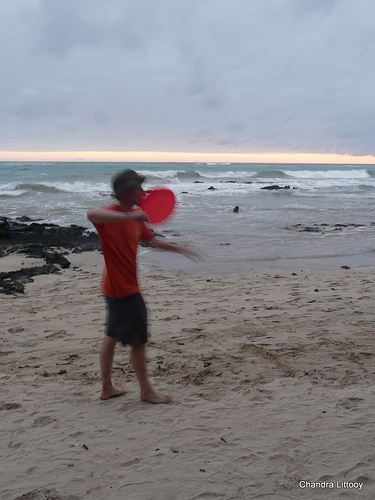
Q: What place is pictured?
A: It is a beach.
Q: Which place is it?
A: It is a beach.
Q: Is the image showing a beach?
A: Yes, it is showing a beach.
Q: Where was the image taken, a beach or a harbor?
A: It was taken at a beach.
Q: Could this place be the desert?
A: No, it is the beach.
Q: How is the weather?
A: It is cloudy.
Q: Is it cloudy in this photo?
A: Yes, it is cloudy.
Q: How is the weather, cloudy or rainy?
A: It is cloudy.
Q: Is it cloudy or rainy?
A: It is cloudy.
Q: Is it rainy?
A: No, it is cloudy.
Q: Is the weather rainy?
A: No, it is cloudy.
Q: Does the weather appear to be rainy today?
A: No, it is cloudy.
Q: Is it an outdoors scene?
A: Yes, it is outdoors.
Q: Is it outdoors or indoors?
A: It is outdoors.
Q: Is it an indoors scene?
A: No, it is outdoors.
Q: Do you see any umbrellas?
A: No, there are no umbrellas.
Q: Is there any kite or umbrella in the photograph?
A: No, there are no umbrellas or kites.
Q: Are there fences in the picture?
A: No, there are no fences.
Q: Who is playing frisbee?
A: The man is playing frisbee.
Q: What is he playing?
A: The man is playing frisbee.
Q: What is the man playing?
A: The man is playing frisbee.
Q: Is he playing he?
A: Yes, the man is playing frisbee.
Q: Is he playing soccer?
A: No, the man is playing frisbee.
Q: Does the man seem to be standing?
A: Yes, the man is standing.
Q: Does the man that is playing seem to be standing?
A: Yes, the man is standing.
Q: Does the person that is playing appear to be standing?
A: Yes, the man is standing.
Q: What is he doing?
A: The man is standing.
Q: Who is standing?
A: The man is standing.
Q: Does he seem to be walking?
A: No, the man is standing.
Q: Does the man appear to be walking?
A: No, the man is standing.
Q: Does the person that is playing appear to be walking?
A: No, the man is standing.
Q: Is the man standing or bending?
A: The man is standing.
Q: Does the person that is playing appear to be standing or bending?
A: The man is standing.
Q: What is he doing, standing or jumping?
A: The man is standing.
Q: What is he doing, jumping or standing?
A: The man is standing.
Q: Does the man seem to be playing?
A: Yes, the man is playing.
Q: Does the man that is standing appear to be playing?
A: Yes, the man is playing.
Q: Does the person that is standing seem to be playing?
A: Yes, the man is playing.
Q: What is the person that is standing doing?
A: The man is playing.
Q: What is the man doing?
A: The man is playing.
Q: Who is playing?
A: The man is playing.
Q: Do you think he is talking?
A: No, the man is playing.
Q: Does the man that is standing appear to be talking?
A: No, the man is playing.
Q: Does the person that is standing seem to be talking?
A: No, the man is playing.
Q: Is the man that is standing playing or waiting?
A: The man is playing.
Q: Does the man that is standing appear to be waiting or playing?
A: The man is playing.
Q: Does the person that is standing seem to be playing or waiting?
A: The man is playing.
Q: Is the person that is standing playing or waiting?
A: The man is playing.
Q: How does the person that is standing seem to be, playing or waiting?
A: The man is playing.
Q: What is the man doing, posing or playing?
A: The man is playing.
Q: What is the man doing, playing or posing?
A: The man is playing.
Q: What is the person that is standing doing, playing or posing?
A: The man is playing.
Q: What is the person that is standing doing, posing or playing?
A: The man is playing.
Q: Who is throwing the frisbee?
A: The man is throwing the frisbee.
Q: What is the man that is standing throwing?
A: The man is throwing the frisbee.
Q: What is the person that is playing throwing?
A: The man is throwing the frisbee.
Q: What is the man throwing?
A: The man is throwing the frisbee.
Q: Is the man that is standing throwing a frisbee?
A: Yes, the man is throwing a frisbee.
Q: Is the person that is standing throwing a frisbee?
A: Yes, the man is throwing a frisbee.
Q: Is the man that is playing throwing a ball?
A: No, the man is throwing a frisbee.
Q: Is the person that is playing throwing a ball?
A: No, the man is throwing a frisbee.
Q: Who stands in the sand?
A: The man stands in the sand.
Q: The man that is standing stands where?
A: The man stands in the sand.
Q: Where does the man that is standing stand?
A: The man stands in the sand.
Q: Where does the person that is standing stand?
A: The man stands in the sand.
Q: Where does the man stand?
A: The man stands in the sand.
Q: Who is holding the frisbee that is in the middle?
A: The man is holding the frisbee.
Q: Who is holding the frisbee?
A: The man is holding the frisbee.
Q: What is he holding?
A: The man is holding the frisbee.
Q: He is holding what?
A: The man is holding the frisbee.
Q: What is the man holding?
A: The man is holding the frisbee.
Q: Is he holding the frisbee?
A: Yes, the man is holding the frisbee.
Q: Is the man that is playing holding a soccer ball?
A: No, the man is holding the frisbee.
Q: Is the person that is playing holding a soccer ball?
A: No, the man is holding the frisbee.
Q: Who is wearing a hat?
A: The man is wearing a hat.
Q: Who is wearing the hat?
A: The man is wearing a hat.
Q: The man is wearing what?
A: The man is wearing a hat.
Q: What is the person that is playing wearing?
A: The man is wearing a hat.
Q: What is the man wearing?
A: The man is wearing a hat.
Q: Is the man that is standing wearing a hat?
A: Yes, the man is wearing a hat.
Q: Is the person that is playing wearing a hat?
A: Yes, the man is wearing a hat.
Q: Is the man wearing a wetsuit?
A: No, the man is wearing a hat.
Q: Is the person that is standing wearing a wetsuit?
A: No, the man is wearing a hat.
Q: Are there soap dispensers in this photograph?
A: No, there are no soap dispensers.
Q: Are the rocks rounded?
A: Yes, the rocks are rounded.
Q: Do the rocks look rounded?
A: Yes, the rocks are rounded.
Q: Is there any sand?
A: Yes, there is sand.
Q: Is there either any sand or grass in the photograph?
A: Yes, there is sand.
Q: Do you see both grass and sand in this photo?
A: No, there is sand but no grass.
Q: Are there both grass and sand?
A: No, there is sand but no grass.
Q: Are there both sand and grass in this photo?
A: No, there is sand but no grass.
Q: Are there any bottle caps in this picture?
A: No, there are no bottle caps.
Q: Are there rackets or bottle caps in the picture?
A: No, there are no bottle caps or rackets.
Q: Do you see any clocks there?
A: No, there are no clocks.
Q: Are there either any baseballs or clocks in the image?
A: No, there are no clocks or baseballs.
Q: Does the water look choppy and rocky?
A: Yes, the water is choppy and rocky.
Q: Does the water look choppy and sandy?
A: No, the water is choppy but rocky.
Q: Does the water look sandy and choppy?
A: No, the water is choppy but rocky.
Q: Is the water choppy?
A: Yes, the water is choppy.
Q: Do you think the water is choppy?
A: Yes, the water is choppy.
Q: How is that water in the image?
A: The water is choppy.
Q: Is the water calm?
A: No, the water is choppy.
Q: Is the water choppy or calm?
A: The water is choppy.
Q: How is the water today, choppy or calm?
A: The water is choppy.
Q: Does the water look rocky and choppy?
A: Yes, the water is rocky and choppy.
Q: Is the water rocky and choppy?
A: Yes, the water is rocky and choppy.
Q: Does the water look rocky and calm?
A: No, the water is rocky but choppy.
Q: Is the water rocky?
A: Yes, the water is rocky.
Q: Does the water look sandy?
A: No, the water is rocky.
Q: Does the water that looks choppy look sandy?
A: No, the water is rocky.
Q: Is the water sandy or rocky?
A: The water is rocky.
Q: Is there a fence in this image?
A: No, there are no fences.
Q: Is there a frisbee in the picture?
A: Yes, there is a frisbee.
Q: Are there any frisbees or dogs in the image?
A: Yes, there is a frisbee.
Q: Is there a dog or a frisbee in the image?
A: Yes, there is a frisbee.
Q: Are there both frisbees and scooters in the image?
A: No, there is a frisbee but no scooters.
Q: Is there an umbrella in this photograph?
A: No, there are no umbrellas.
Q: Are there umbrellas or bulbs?
A: No, there are no umbrellas or bulbs.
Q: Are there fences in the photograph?
A: No, there are no fences.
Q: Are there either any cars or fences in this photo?
A: No, there are no fences or cars.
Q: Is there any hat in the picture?
A: Yes, there is a hat.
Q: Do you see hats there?
A: Yes, there is a hat.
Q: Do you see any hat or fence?
A: Yes, there is a hat.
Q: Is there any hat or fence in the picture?
A: Yes, there is a hat.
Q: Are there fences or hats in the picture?
A: Yes, there is a hat.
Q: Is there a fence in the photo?
A: No, there are no fences.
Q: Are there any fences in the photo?
A: No, there are no fences.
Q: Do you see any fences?
A: No, there are no fences.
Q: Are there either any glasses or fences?
A: No, there are no fences or glasses.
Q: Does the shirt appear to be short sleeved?
A: Yes, the shirt is short sleeved.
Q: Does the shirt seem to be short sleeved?
A: Yes, the shirt is short sleeved.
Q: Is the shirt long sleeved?
A: No, the shirt is short sleeved.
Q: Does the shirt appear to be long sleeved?
A: No, the shirt is short sleeved.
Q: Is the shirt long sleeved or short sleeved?
A: The shirt is short sleeved.